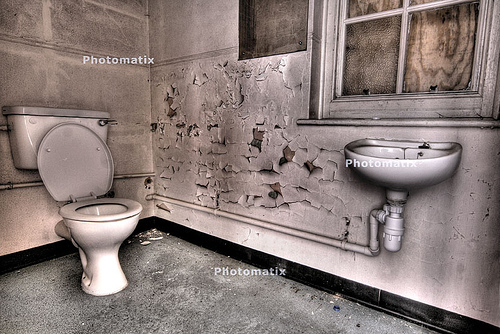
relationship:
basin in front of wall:
[342, 137, 463, 190] [150, 1, 499, 329]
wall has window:
[150, 1, 499, 329] [323, 1, 495, 117]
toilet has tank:
[36, 120, 142, 296] [3, 106, 111, 169]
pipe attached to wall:
[145, 192, 380, 259] [150, 1, 499, 329]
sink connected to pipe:
[343, 137, 462, 202] [145, 192, 380, 259]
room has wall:
[0, 0, 499, 333] [150, 1, 499, 329]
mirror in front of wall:
[238, 1, 307, 60] [150, 1, 499, 329]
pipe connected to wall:
[145, 192, 380, 259] [150, 1, 499, 329]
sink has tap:
[343, 137, 462, 202] [418, 139, 430, 149]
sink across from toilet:
[343, 137, 462, 202] [36, 120, 142, 296]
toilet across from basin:
[36, 120, 142, 296] [342, 137, 463, 190]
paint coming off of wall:
[156, 60, 345, 216] [150, 1, 499, 329]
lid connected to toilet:
[36, 121, 115, 201] [36, 120, 142, 296]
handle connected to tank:
[99, 119, 117, 127] [3, 106, 111, 169]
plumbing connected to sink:
[145, 192, 383, 258] [343, 137, 462, 202]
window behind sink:
[323, 1, 495, 117] [343, 137, 462, 202]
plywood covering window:
[342, 0, 477, 95] [323, 1, 495, 117]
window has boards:
[323, 1, 495, 117] [342, 1, 477, 94]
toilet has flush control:
[36, 120, 142, 296] [96, 119, 116, 126]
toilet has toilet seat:
[36, 120, 142, 296] [58, 196, 143, 222]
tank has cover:
[3, 106, 111, 169] [1, 105, 113, 120]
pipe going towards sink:
[145, 192, 380, 259] [343, 137, 462, 202]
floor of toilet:
[1, 226, 439, 333] [6, 90, 178, 314]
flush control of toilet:
[96, 119, 116, 126] [8, 94, 174, 264]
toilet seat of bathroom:
[58, 196, 143, 222] [0, 57, 483, 327]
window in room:
[323, 1, 495, 117] [5, 54, 499, 254]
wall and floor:
[150, 1, 499, 329] [1, 226, 439, 333]